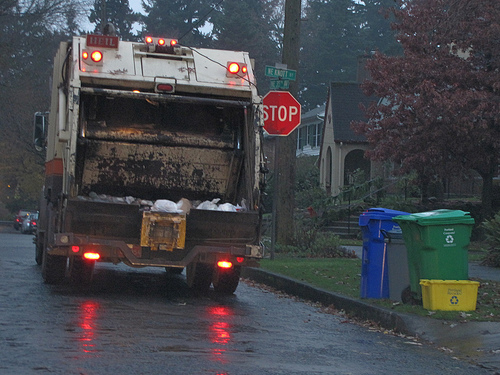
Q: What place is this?
A: It is a road.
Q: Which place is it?
A: It is a road.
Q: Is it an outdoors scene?
A: Yes, it is outdoors.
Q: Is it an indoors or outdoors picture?
A: It is outdoors.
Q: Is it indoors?
A: No, it is outdoors.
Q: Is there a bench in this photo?
A: No, there are no benches.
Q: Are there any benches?
A: No, there are no benches.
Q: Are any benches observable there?
A: No, there are no benches.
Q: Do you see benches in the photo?
A: No, there are no benches.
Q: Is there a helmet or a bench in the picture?
A: No, there are no benches or helmets.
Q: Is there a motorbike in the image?
A: No, there are no motorcycles.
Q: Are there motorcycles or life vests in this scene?
A: No, there are no motorcycles or life vests.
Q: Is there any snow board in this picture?
A: No, there are no snowboards.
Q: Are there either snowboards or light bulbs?
A: No, there are no snowboards or light bulbs.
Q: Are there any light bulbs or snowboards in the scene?
A: No, there are no snowboards or light bulbs.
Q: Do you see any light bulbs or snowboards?
A: No, there are no snowboards or light bulbs.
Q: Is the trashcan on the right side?
A: Yes, the trashcan is on the right of the image.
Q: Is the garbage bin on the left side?
A: No, the garbage bin is on the right of the image.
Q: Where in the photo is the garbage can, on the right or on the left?
A: The garbage can is on the right of the image.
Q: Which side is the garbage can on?
A: The garbage can is on the right of the image.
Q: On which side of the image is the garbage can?
A: The garbage can is on the right of the image.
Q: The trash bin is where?
A: The trash bin is on the grass.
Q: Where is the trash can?
A: The trash bin is on the grass.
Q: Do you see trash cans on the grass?
A: Yes, there is a trash can on the grass.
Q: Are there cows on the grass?
A: No, there is a trash can on the grass.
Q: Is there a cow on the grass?
A: No, there is a trash can on the grass.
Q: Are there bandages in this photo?
A: No, there are no bandages.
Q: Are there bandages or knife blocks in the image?
A: No, there are no bandages or knife blocks.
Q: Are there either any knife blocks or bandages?
A: No, there are no bandages or knife blocks.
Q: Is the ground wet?
A: Yes, the ground is wet.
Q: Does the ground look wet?
A: Yes, the ground is wet.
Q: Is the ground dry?
A: No, the ground is wet.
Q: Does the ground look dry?
A: No, the ground is wet.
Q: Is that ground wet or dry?
A: The ground is wet.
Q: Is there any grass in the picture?
A: Yes, there is grass.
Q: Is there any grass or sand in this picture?
A: Yes, there is grass.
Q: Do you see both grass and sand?
A: No, there is grass but no sand.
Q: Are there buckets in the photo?
A: No, there are no buckets.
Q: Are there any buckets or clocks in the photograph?
A: No, there are no buckets or clocks.